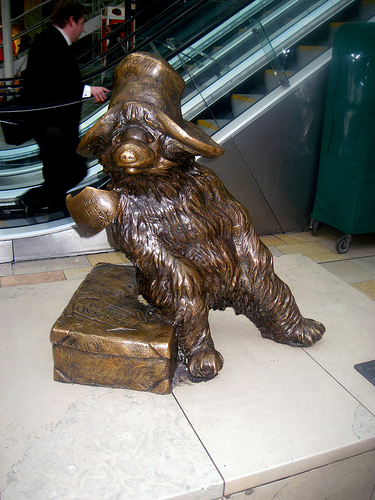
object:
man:
[14, 1, 110, 225]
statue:
[65, 50, 327, 384]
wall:
[276, 108, 295, 140]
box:
[49, 261, 178, 395]